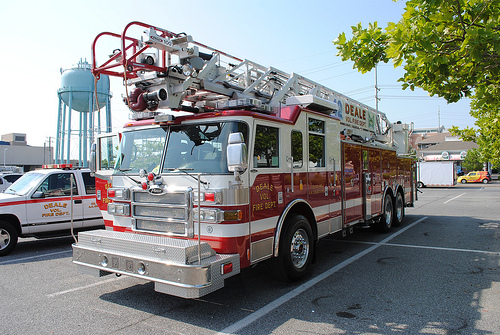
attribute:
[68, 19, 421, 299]
fire truck — parked, red, white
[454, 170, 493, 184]
vehicle — yellow, orange, parked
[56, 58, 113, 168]
tower — blue, large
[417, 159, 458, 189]
trailer — white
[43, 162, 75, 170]
siren — white, red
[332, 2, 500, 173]
tree — green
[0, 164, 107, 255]
vehicle — parked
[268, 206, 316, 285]
tire — black, round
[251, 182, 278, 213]
lettering — orange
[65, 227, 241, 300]
bumper — chrome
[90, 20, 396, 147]
ladder — folded down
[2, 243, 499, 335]
lines — white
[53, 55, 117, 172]
water tower — blue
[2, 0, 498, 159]
sky — blue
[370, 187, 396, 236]
tire — rear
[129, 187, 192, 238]
grill — silver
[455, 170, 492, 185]
suv — yellow, orange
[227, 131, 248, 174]
mirror — driver's side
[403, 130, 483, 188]
building — tan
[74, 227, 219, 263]
box — silver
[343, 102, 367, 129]
writing — red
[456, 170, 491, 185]
car — yellow, orange